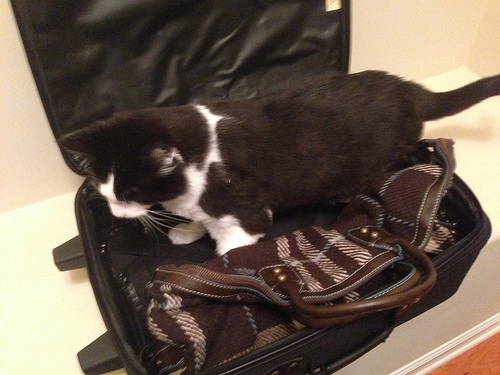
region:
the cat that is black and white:
[65, 96, 367, 296]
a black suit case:
[28, 83, 498, 315]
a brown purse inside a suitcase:
[189, 262, 346, 303]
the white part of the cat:
[189, 101, 232, 161]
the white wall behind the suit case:
[404, 19, 472, 68]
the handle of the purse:
[289, 287, 469, 318]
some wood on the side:
[477, 350, 487, 374]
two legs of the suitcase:
[39, 235, 111, 374]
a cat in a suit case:
[101, 113, 345, 227]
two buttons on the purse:
[266, 240, 301, 288]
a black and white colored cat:
[61, 51, 498, 262]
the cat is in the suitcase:
[71, 67, 498, 240]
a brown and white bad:
[134, 137, 473, 372]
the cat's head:
[51, 108, 168, 218]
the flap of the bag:
[8, 0, 379, 188]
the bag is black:
[1, 0, 497, 374]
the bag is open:
[0, 0, 492, 374]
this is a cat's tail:
[413, 57, 498, 118]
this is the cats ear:
[155, 130, 190, 186]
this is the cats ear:
[55, 116, 111, 178]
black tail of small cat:
[403, 76, 493, 118]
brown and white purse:
[152, 139, 459, 374]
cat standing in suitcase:
[4, 0, 492, 365]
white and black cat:
[60, 69, 499, 257]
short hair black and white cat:
[64, 67, 499, 254]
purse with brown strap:
[260, 228, 435, 313]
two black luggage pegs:
[45, 236, 118, 371]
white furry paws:
[166, 217, 258, 254]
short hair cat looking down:
[62, 47, 498, 252]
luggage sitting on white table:
[0, 1, 497, 373]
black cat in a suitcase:
[42, 44, 498, 259]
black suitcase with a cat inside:
[7, 4, 492, 374]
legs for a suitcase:
[47, 226, 120, 373]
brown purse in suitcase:
[144, 171, 478, 373]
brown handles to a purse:
[278, 246, 453, 326]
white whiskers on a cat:
[137, 205, 192, 242]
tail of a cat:
[412, 69, 498, 129]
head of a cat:
[55, 115, 195, 225]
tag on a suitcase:
[317, 0, 344, 21]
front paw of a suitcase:
[164, 214, 211, 251]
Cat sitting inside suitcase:
[55, 65, 496, 267]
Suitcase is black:
[12, 0, 492, 374]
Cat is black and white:
[56, 63, 498, 249]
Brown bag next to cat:
[138, 130, 460, 372]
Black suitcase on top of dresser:
[5, 0, 490, 370]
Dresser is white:
[0, 52, 497, 373]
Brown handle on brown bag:
[270, 225, 445, 321]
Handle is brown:
[275, 240, 445, 316]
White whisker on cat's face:
[140, 205, 200, 230]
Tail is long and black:
[416, 55, 496, 135]